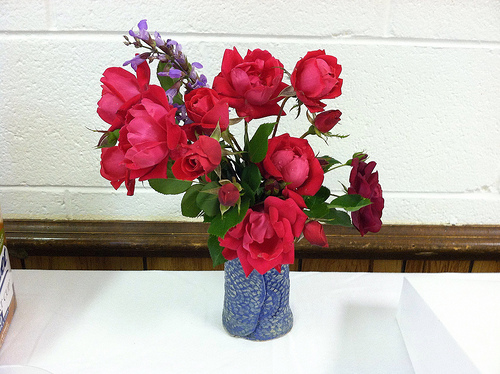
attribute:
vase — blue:
[209, 243, 302, 348]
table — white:
[16, 268, 499, 370]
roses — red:
[87, 11, 375, 251]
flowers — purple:
[129, 21, 219, 105]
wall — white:
[0, 0, 500, 229]